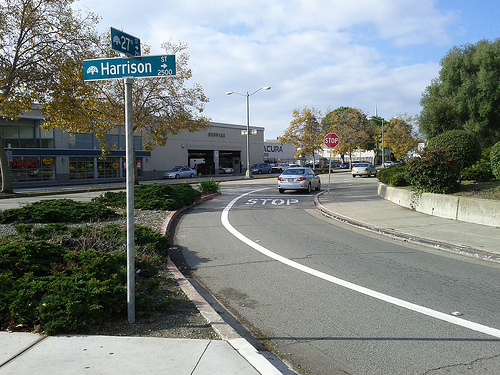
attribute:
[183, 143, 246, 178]
garages — open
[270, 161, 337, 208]
car — silver 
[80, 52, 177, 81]
street sign — green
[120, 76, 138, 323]
post — galvanized steel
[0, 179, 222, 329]
shrubs — green 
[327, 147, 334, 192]
post — galvanized steel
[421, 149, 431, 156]
flowers — red 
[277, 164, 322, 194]
sedan — small, silver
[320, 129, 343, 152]
stop sign — red, white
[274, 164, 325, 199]
car — grey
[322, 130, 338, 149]
stop sign — red 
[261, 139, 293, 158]
acura building — white 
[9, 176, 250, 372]
corner — curved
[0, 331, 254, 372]
cement — grey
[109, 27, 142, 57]
street sign — green